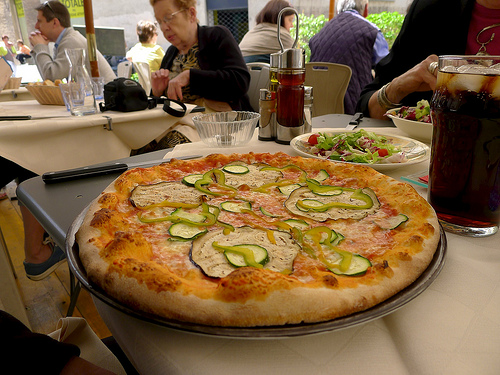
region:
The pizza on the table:
[50, 105, 456, 364]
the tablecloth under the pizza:
[118, 133, 498, 361]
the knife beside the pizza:
[43, 136, 203, 185]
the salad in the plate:
[296, 113, 433, 183]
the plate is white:
[286, 110, 441, 175]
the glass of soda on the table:
[421, 43, 498, 245]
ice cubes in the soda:
[448, 55, 498, 94]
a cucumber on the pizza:
[218, 234, 278, 274]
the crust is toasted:
[86, 194, 193, 312]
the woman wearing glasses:
[134, 6, 244, 111]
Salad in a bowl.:
[299, 115, 426, 171]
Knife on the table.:
[341, 108, 376, 135]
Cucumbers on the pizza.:
[216, 238, 361, 277]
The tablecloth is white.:
[400, 270, 493, 370]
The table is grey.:
[33, 173, 100, 221]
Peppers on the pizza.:
[162, 168, 288, 233]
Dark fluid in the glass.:
[435, 52, 497, 218]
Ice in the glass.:
[438, 60, 498, 97]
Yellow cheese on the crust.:
[100, 204, 186, 303]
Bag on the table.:
[101, 77, 187, 119]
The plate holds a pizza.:
[65, 150, 445, 342]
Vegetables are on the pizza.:
[188, 224, 300, 284]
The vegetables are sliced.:
[187, 225, 297, 285]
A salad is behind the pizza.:
[306, 126, 405, 163]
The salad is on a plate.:
[290, 126, 427, 168]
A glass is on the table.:
[427, 55, 499, 237]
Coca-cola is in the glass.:
[432, 88, 498, 223]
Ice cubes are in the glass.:
[438, 65, 498, 90]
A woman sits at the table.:
[147, 0, 251, 101]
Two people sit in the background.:
[236, 0, 394, 112]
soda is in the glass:
[434, 43, 496, 225]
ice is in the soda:
[437, 57, 497, 100]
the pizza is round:
[62, 142, 444, 335]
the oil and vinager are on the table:
[267, 44, 308, 143]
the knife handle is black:
[37, 155, 127, 187]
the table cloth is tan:
[432, 297, 474, 347]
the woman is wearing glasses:
[148, 10, 188, 30]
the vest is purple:
[298, 10, 383, 57]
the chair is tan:
[311, 57, 353, 111]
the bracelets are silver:
[372, 77, 397, 110]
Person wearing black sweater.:
[197, 29, 248, 91]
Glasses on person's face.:
[152, 20, 187, 29]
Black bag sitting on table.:
[103, 65, 175, 140]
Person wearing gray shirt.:
[38, 33, 138, 87]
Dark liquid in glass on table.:
[451, 73, 487, 183]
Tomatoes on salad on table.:
[308, 129, 393, 162]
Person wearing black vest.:
[331, 27, 371, 97]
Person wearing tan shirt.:
[248, 24, 289, 56]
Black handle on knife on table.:
[46, 163, 142, 182]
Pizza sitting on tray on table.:
[81, 141, 436, 315]